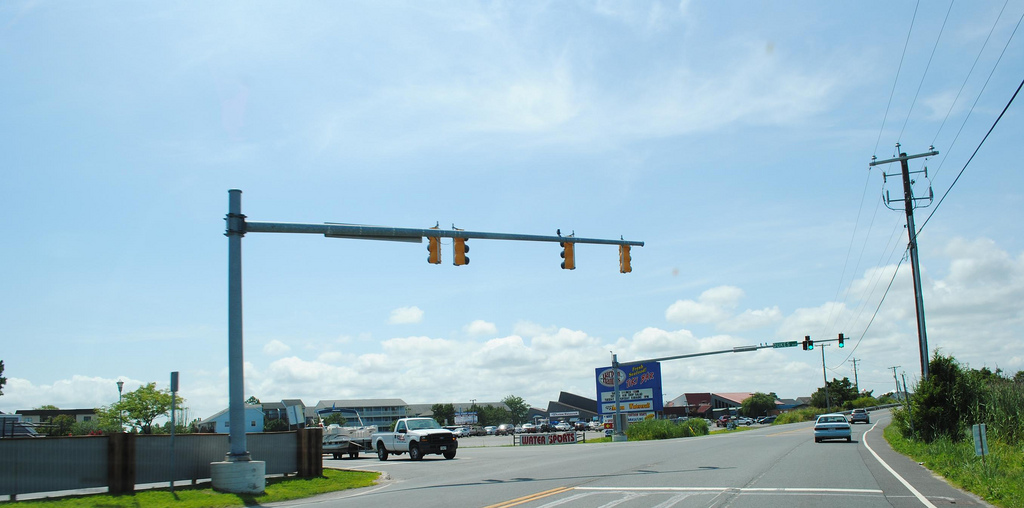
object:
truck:
[361, 410, 467, 469]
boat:
[314, 401, 379, 440]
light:
[613, 242, 633, 275]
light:
[555, 229, 577, 269]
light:
[447, 233, 471, 268]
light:
[419, 222, 446, 266]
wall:
[594, 351, 677, 425]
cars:
[818, 390, 872, 466]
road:
[618, 452, 826, 500]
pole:
[216, 234, 273, 496]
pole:
[224, 197, 263, 491]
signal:
[432, 227, 638, 267]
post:
[222, 204, 254, 457]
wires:
[247, 1, 991, 364]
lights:
[413, 224, 651, 272]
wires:
[829, 0, 1007, 223]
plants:
[904, 361, 1017, 504]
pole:
[205, 449, 281, 501]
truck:
[372, 405, 460, 460]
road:
[291, 407, 913, 503]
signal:
[417, 214, 439, 264]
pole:
[178, 175, 658, 474]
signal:
[446, 229, 478, 268]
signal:
[550, 229, 596, 279]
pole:
[208, 173, 673, 459]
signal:
[614, 234, 661, 306]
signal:
[830, 314, 857, 351]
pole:
[608, 318, 881, 435]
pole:
[607, 355, 623, 444]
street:
[284, 392, 1006, 503]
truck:
[373, 413, 452, 459]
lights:
[419, 225, 633, 273]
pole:
[221, 182, 645, 459]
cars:
[808, 394, 876, 446]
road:
[284, 394, 991, 503]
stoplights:
[424, 227, 451, 262]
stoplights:
[449, 232, 476, 267]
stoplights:
[555, 234, 582, 276]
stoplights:
[613, 243, 635, 276]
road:
[277, 379, 1003, 501]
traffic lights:
[791, 317, 854, 357]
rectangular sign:
[477, 419, 592, 458]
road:
[476, 397, 778, 508]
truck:
[370, 413, 461, 461]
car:
[814, 413, 853, 440]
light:
[619, 238, 633, 275]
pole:
[224, 188, 649, 435]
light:
[556, 238, 576, 269]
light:
[425, 234, 445, 265]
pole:
[210, 188, 646, 491]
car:
[494, 424, 516, 436]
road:
[473, 452, 525, 476]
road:
[463, 435, 583, 488]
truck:
[388, 441, 451, 470]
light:
[291, 186, 633, 275]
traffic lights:
[394, 210, 682, 301]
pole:
[169, 173, 336, 424]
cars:
[791, 411, 917, 461]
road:
[663, 428, 800, 493]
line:
[539, 465, 890, 502]